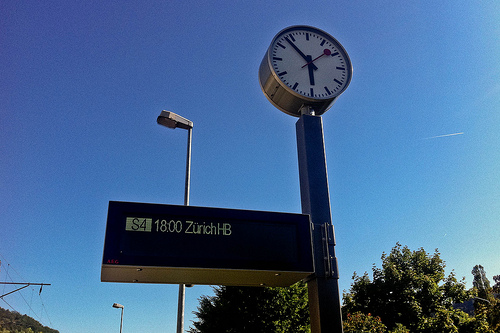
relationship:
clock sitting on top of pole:
[257, 24, 353, 119] [293, 114, 346, 332]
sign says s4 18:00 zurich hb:
[99, 200, 314, 291] [125, 216, 233, 238]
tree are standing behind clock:
[185, 281, 314, 333] [257, 24, 353, 119]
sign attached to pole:
[99, 200, 314, 291] [293, 114, 346, 332]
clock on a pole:
[257, 24, 353, 119] [293, 114, 346, 332]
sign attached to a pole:
[99, 200, 314, 291] [293, 114, 346, 332]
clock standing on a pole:
[257, 24, 353, 119] [293, 114, 346, 332]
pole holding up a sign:
[293, 114, 346, 332] [99, 200, 314, 291]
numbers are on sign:
[139, 218, 183, 233] [99, 200, 314, 291]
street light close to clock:
[156, 106, 195, 332] [257, 24, 353, 119]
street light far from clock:
[112, 301, 127, 333] [257, 24, 353, 119]